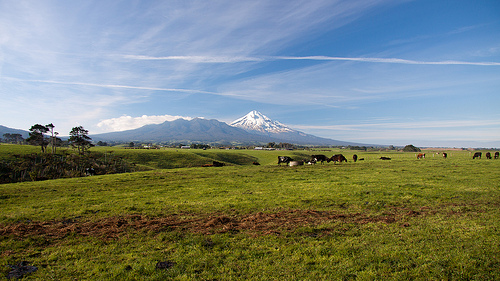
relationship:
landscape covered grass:
[54, 172, 467, 274] [108, 167, 360, 192]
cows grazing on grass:
[275, 150, 356, 171] [4, 147, 498, 278]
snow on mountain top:
[229, 107, 289, 136] [225, 107, 295, 134]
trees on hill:
[25, 120, 93, 153] [2, 144, 252, 185]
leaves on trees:
[31, 123, 91, 143] [25, 120, 93, 153]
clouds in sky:
[3, 3, 497, 145] [0, 3, 497, 147]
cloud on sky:
[61, 57, 201, 105] [0, 3, 497, 147]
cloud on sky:
[76, 54, 245, 105] [0, 3, 497, 147]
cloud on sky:
[61, 46, 217, 123] [0, 3, 497, 147]